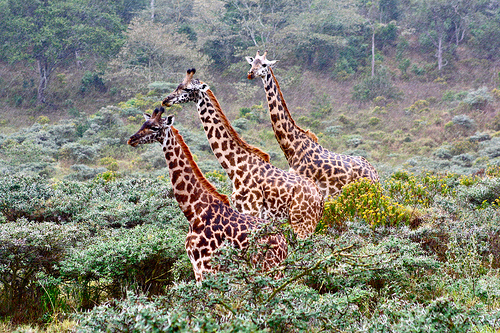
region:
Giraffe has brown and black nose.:
[126, 127, 146, 162]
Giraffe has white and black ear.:
[155, 115, 177, 125]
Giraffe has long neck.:
[155, 130, 225, 220]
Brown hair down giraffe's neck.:
[165, 125, 215, 200]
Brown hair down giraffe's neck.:
[198, 78, 275, 186]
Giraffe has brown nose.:
[239, 61, 261, 94]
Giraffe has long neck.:
[273, 77, 310, 160]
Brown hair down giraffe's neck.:
[267, 81, 302, 123]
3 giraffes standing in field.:
[157, 75, 384, 275]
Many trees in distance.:
[53, 14, 384, 44]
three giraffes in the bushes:
[90, 40, 412, 281]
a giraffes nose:
[116, 131, 144, 154]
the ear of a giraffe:
[268, 53, 285, 70]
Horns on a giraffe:
[252, 45, 268, 56]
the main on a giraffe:
[202, 85, 268, 166]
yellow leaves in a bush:
[316, 172, 404, 233]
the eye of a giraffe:
[257, 61, 267, 69]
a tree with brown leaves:
[103, 20, 214, 91]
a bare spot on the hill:
[303, 72, 344, 95]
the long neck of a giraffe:
[259, 75, 319, 161]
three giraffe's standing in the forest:
[106, 30, 389, 303]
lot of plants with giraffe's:
[67, 123, 439, 313]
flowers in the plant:
[337, 175, 414, 235]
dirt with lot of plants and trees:
[338, 34, 475, 156]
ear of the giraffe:
[166, 110, 174, 130]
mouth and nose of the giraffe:
[123, 128, 145, 148]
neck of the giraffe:
[153, 96, 283, 162]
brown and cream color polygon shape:
[177, 160, 250, 254]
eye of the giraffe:
[258, 61, 270, 69]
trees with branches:
[311, 11, 478, 65]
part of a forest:
[368, 274, 383, 311]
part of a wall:
[300, 92, 307, 103]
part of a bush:
[292, 273, 300, 288]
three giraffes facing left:
[119, 40, 394, 281]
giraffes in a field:
[5, 36, 496, 329]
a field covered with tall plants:
[10, 95, 490, 330]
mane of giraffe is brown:
[267, 65, 317, 136]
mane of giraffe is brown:
[205, 81, 276, 165]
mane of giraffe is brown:
[168, 126, 230, 220]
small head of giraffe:
[237, 45, 278, 85]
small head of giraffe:
[159, 62, 213, 109]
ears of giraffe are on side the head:
[136, 101, 181, 132]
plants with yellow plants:
[309, 159, 463, 233]